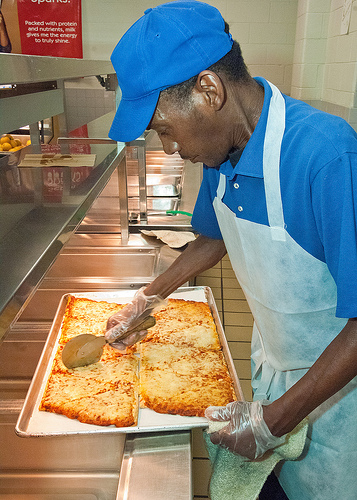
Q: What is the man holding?
A: A pizza tray.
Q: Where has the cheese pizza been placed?
A: On a tray.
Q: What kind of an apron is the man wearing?
A: A paper apron.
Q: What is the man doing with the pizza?
A: Cutting it.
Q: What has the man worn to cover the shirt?
A: An apron.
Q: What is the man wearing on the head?
A: A blue cap.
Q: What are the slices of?
A: Cheese pizza.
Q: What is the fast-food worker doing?
A: Cutting pizza.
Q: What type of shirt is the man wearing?
A: A blue polo shirt.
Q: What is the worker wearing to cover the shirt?
A: A white apron.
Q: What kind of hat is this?
A: This is a blue hat.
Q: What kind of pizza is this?
A: This is cheese pizza.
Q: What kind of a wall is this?
A: A cream wall.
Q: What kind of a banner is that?
A: A red banner.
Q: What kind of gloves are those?
A: Plastic gloves.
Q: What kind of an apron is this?
A: A paper apron.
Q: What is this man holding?
A: A pizza cutter.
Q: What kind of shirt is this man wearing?
A: A blue shirt.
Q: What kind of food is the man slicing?
A: Pizza.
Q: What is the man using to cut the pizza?
A: Pizza Slicer.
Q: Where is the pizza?
A: On a baking sheet.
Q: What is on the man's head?
A: A hat.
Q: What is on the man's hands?
A: Gloves.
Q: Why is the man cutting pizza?
A: To serve it.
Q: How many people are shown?
A: One.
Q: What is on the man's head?
A: Cap.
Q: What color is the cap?
A: Blue.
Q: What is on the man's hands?
A: Gloves.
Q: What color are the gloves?
A: Clear.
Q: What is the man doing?
A: Cutting pizza.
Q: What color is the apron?
A: White.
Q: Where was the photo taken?
A: In a kitchen.